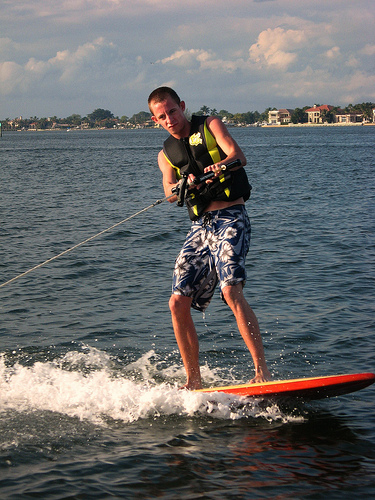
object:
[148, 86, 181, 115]
hair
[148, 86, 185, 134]
head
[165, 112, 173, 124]
nose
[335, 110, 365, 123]
building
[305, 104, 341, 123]
building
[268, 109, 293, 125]
building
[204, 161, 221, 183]
hands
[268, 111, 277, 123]
wall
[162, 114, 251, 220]
vest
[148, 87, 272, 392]
boy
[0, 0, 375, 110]
cloud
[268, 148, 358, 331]
water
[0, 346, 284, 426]
waves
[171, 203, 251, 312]
shorts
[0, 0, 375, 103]
sky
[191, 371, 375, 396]
board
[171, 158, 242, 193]
handlebars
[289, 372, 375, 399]
part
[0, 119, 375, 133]
shore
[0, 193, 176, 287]
cord